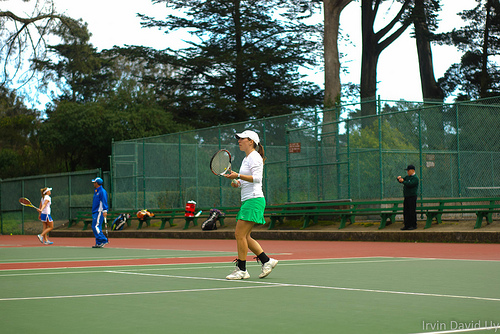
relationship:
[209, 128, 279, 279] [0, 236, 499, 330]
woman on tennis court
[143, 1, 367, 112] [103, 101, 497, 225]
trees behind fence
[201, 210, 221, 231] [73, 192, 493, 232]
bag on bench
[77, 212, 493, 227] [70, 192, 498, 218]
legs on bench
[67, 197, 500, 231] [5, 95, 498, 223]
bench in front fence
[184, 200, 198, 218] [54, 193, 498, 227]
bag on bench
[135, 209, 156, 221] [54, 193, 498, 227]
bag on bench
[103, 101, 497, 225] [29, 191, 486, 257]
fence behind bench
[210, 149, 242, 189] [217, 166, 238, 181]
racket in hand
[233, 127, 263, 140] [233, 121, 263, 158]
cap on head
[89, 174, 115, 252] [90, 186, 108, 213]
man in blue clothes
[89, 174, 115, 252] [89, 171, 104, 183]
man in hat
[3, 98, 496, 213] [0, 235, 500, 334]
fence surrounding tennis court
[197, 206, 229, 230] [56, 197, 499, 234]
bag lean bench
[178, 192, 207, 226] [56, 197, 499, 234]
bag lean bench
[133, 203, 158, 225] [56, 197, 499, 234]
bag lean bench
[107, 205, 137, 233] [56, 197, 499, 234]
bag lean bench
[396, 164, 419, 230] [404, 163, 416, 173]
man wearing hat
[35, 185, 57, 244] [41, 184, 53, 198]
woman wearing visor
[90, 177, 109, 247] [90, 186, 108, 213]
man in blue clothes